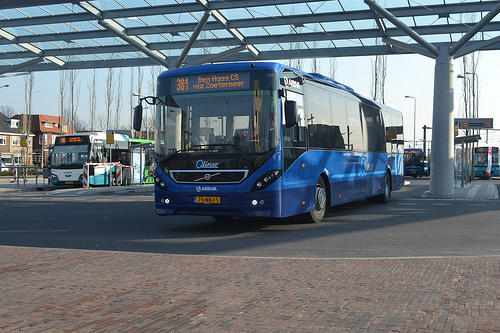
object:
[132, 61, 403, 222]
bus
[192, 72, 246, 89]
sign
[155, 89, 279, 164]
windshield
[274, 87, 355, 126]
window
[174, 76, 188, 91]
number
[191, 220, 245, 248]
shadow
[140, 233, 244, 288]
ground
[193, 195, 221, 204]
plate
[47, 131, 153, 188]
bus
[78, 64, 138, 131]
tree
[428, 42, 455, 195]
column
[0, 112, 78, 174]
house